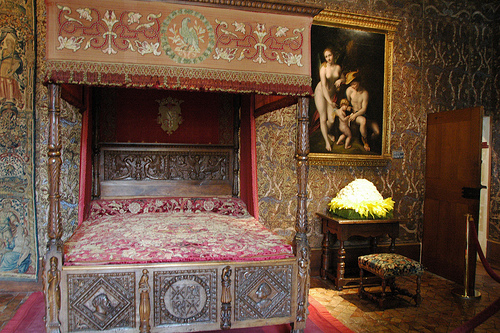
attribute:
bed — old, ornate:
[58, 143, 300, 333]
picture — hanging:
[308, 6, 400, 169]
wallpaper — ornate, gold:
[258, 1, 499, 252]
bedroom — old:
[2, 2, 499, 332]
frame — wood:
[42, 85, 306, 333]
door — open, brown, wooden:
[421, 106, 500, 290]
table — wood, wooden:
[316, 210, 400, 287]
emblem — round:
[159, 273, 211, 326]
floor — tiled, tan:
[307, 260, 500, 331]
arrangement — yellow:
[328, 177, 397, 219]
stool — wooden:
[354, 251, 425, 311]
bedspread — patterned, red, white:
[64, 197, 297, 267]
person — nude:
[314, 45, 344, 151]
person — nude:
[335, 100, 354, 150]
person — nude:
[345, 72, 381, 151]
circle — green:
[159, 6, 216, 65]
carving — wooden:
[99, 149, 232, 184]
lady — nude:
[313, 45, 343, 152]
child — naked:
[336, 100, 355, 150]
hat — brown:
[342, 67, 362, 85]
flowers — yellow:
[327, 179, 395, 223]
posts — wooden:
[46, 82, 310, 235]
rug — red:
[2, 290, 353, 332]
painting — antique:
[300, 6, 403, 167]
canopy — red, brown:
[43, 2, 329, 102]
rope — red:
[470, 219, 499, 282]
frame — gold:
[297, 7, 402, 173]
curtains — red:
[78, 86, 259, 218]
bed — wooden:
[45, 2, 323, 332]